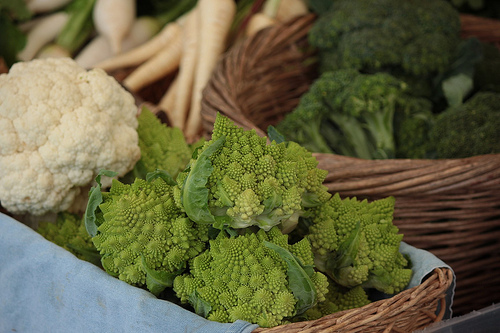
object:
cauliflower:
[0, 54, 147, 215]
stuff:
[171, 110, 331, 232]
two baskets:
[2, 1, 499, 332]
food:
[333, 69, 401, 150]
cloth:
[0, 212, 459, 332]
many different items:
[92, 0, 131, 53]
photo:
[0, 0, 500, 332]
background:
[1, 1, 498, 165]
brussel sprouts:
[91, 172, 211, 291]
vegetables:
[174, 234, 335, 328]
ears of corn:
[189, 0, 232, 134]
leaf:
[189, 139, 223, 228]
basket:
[201, 8, 500, 193]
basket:
[1, 60, 457, 331]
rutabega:
[96, 19, 178, 70]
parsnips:
[19, 6, 81, 60]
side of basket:
[0, 271, 113, 332]